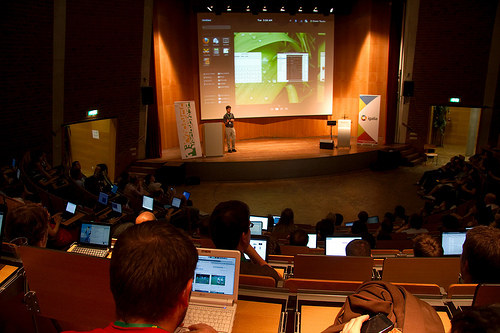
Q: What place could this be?
A: It is a classroom.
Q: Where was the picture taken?
A: It was taken at the classroom.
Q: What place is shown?
A: It is a classroom.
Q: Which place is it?
A: It is a classroom.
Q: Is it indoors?
A: Yes, it is indoors.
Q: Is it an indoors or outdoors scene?
A: It is indoors.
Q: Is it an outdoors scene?
A: No, it is indoors.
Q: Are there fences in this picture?
A: No, there are no fences.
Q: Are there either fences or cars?
A: No, there are no fences or cars.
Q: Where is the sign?
A: The sign is on the stage.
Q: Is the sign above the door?
A: Yes, the sign is above the door.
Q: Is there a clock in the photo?
A: No, there are no clocks.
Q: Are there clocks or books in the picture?
A: No, there are no clocks or books.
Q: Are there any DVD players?
A: No, there are no DVD players.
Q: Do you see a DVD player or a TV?
A: No, there are no DVD players or televisions.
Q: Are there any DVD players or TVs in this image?
A: No, there are no DVD players or tvs.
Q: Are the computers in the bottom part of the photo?
A: Yes, the computers are in the bottom of the image.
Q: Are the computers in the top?
A: No, the computers are in the bottom of the image.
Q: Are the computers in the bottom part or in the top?
A: The computers are in the bottom of the image.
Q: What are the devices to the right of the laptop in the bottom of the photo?
A: The devices are computers.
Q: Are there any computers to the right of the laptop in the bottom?
A: Yes, there are computers to the right of the laptop.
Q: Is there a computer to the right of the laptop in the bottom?
A: Yes, there are computers to the right of the laptop.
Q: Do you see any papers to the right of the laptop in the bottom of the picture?
A: No, there are computers to the right of the laptop computer.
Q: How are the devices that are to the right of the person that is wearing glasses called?
A: The devices are computers.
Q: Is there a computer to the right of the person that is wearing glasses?
A: Yes, there are computers to the right of the person.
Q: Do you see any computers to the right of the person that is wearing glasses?
A: Yes, there are computers to the right of the person.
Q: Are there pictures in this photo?
A: No, there are no pictures.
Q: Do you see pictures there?
A: No, there are no pictures.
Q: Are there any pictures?
A: No, there are no pictures.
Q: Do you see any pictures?
A: No, there are no pictures.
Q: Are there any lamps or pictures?
A: No, there are no pictures or lamps.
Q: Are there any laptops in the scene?
A: Yes, there are laptops.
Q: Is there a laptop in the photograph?
A: Yes, there are laptops.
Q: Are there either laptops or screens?
A: Yes, there are laptops.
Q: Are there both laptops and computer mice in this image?
A: No, there are laptops but no computer mice.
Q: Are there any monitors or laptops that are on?
A: Yes, the laptops are on.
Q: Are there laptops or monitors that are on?
A: Yes, the laptops are on.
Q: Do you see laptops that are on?
A: Yes, there are laptops that are on.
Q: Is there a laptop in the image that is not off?
A: Yes, there are laptops that are on.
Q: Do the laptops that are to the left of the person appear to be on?
A: Yes, the laptops are on.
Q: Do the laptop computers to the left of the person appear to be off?
A: No, the laptops are on.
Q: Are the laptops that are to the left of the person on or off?
A: The laptops are on.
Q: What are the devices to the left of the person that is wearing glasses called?
A: The devices are laptops.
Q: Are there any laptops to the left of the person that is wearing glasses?
A: Yes, there are laptops to the left of the person.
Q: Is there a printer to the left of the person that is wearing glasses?
A: No, there are laptops to the left of the person.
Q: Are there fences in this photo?
A: No, there are no fences.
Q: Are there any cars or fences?
A: No, there are no fences or cars.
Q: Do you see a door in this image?
A: Yes, there is a door.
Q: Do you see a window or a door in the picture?
A: Yes, there is a door.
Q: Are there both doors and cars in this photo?
A: No, there is a door but no cars.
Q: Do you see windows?
A: No, there are no windows.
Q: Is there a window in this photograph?
A: No, there are no windows.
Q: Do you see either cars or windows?
A: No, there are no windows or cars.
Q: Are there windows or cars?
A: No, there are no windows or cars.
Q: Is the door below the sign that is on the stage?
A: Yes, the door is below the sign.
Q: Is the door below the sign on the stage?
A: Yes, the door is below the sign.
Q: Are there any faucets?
A: No, there are no faucets.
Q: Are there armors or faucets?
A: No, there are no faucets or armors.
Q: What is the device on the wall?
A: The device is a screen.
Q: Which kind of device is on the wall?
A: The device is a screen.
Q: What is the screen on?
A: The screen is on the wall.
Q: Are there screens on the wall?
A: Yes, there is a screen on the wall.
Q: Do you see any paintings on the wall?
A: No, there is a screen on the wall.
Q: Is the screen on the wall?
A: Yes, the screen is on the wall.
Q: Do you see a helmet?
A: No, there are no helmets.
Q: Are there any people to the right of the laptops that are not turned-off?
A: Yes, there is a person to the right of the laptops.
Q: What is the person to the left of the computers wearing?
A: The person is wearing glasses.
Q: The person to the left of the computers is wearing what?
A: The person is wearing glasses.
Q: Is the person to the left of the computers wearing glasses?
A: Yes, the person is wearing glasses.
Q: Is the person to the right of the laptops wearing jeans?
A: No, the person is wearing glasses.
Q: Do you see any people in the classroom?
A: Yes, there is a person in the classroom.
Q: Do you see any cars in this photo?
A: No, there are no cars.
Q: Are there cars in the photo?
A: No, there are no cars.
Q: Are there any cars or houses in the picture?
A: No, there are no cars or houses.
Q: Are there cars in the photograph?
A: No, there are no cars.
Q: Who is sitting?
A: The people are sitting.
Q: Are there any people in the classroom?
A: Yes, there are people in the classroom.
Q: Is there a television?
A: No, there are no televisions.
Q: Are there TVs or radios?
A: No, there are no TVs or radios.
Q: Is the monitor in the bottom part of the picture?
A: Yes, the monitor is in the bottom of the image.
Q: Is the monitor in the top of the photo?
A: No, the monitor is in the bottom of the image.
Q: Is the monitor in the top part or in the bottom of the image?
A: The monitor is in the bottom of the image.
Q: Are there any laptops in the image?
A: Yes, there is a laptop.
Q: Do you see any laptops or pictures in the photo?
A: Yes, there is a laptop.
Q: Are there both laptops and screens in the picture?
A: Yes, there are both a laptop and a screen.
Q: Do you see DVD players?
A: No, there are no DVD players.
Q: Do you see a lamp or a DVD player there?
A: No, there are no DVD players or lamps.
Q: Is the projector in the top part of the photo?
A: Yes, the projector is in the top of the image.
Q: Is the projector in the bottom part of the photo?
A: No, the projector is in the top of the image.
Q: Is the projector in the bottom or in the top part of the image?
A: The projector is in the top of the image.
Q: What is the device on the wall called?
A: The device is a projector.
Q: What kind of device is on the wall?
A: The device is a projector.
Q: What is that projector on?
A: The projector is on the wall.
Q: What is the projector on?
A: The projector is on the wall.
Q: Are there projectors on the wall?
A: Yes, there is a projector on the wall.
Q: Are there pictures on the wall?
A: No, there is a projector on the wall.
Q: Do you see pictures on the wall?
A: No, there is a projector on the wall.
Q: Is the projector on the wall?
A: Yes, the projector is on the wall.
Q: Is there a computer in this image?
A: Yes, there is a computer.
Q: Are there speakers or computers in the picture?
A: Yes, there is a computer.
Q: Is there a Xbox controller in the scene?
A: No, there are no Xbox controllers.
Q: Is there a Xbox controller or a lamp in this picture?
A: No, there are no Xbox controllers or lamps.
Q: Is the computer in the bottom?
A: Yes, the computer is in the bottom of the image.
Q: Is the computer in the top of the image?
A: No, the computer is in the bottom of the image.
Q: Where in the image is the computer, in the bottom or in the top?
A: The computer is in the bottom of the image.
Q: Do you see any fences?
A: No, there are no fences.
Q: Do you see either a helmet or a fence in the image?
A: No, there are no fences or helmets.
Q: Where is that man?
A: The man is on the stage.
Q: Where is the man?
A: The man is on the stage.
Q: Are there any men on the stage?
A: Yes, there is a man on the stage.